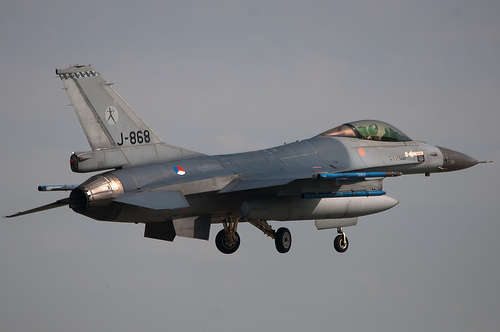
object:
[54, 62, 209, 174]
vertical stabilizer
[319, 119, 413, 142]
cockpit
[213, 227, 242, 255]
wheels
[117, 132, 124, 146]
letter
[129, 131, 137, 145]
number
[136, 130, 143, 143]
number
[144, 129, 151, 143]
number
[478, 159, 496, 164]
nose point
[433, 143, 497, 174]
nose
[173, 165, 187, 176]
logo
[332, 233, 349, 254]
wheel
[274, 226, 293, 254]
wheel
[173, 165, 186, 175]
circle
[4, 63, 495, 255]
jet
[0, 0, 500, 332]
sky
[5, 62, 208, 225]
tail